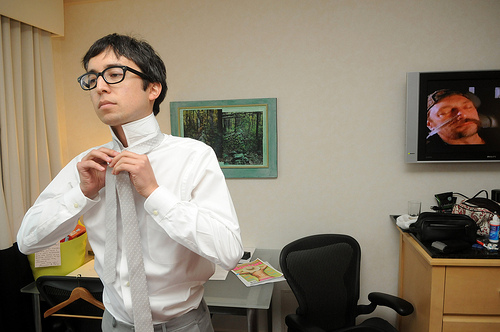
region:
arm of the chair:
[363, 285, 417, 313]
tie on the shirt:
[111, 169, 152, 330]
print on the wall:
[174, 90, 277, 175]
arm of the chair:
[286, 313, 308, 330]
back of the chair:
[276, 225, 367, 325]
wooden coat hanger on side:
[43, 280, 125, 322]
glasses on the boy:
[75, 59, 142, 89]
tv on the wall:
[400, 60, 495, 168]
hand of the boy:
[111, 154, 160, 189]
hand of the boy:
[72, 139, 123, 205]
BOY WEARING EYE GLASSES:
[74, 68, 126, 85]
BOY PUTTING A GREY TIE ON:
[112, 176, 124, 201]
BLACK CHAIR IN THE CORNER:
[280, 231, 361, 331]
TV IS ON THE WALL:
[415, 63, 490, 157]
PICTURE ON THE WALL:
[226, 108, 270, 161]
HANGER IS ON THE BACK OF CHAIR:
[65, 281, 96, 321]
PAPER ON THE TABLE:
[246, 256, 259, 291]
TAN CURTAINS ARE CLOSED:
[5, 92, 50, 136]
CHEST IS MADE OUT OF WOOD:
[450, 285, 465, 310]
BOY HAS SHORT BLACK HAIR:
[133, 40, 145, 59]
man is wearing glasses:
[64, 63, 172, 98]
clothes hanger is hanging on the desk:
[39, 266, 128, 329]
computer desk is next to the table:
[283, 234, 399, 329]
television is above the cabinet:
[378, 69, 496, 182]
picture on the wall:
[159, 89, 301, 209]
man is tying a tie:
[90, 134, 179, 330]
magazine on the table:
[224, 243, 288, 295]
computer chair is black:
[255, 210, 403, 330]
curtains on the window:
[6, 18, 76, 257]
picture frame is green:
[161, 95, 290, 181]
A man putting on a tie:
[16, 33, 241, 330]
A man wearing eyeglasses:
[16, 32, 243, 328]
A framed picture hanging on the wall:
[170, 95, 278, 177]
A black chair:
[281, 233, 414, 329]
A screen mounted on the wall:
[405, 67, 498, 163]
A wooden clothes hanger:
[42, 273, 107, 318]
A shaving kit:
[418, 213, 478, 244]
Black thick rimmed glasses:
[79, 64, 165, 90]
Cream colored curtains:
[0, 16, 64, 250]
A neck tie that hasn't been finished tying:
[103, 154, 152, 329]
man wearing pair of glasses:
[58, 30, 185, 142]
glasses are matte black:
[57, 44, 171, 109]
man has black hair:
[75, 30, 173, 139]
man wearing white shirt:
[36, 99, 249, 297]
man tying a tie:
[75, 128, 185, 324]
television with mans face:
[385, 36, 499, 192]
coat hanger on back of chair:
[27, 263, 123, 325]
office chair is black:
[257, 214, 419, 321]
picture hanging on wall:
[155, 82, 294, 195]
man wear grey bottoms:
[93, 286, 215, 330]